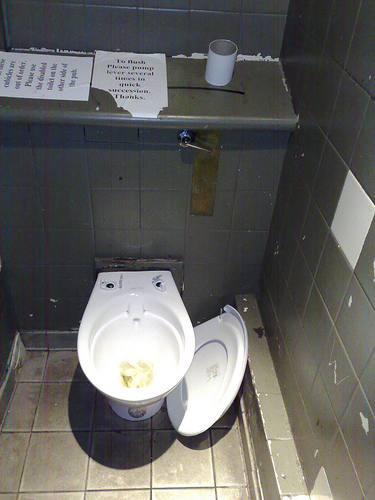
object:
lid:
[166, 303, 252, 438]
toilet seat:
[77, 267, 196, 404]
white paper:
[90, 48, 169, 118]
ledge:
[246, 68, 285, 112]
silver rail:
[204, 39, 240, 88]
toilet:
[76, 270, 196, 421]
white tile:
[329, 168, 374, 269]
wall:
[279, 0, 373, 500]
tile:
[97, 142, 128, 185]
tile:
[93, 187, 133, 223]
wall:
[0, 156, 258, 276]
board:
[190, 130, 221, 217]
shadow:
[106, 424, 148, 451]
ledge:
[259, 367, 278, 398]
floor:
[38, 433, 83, 487]